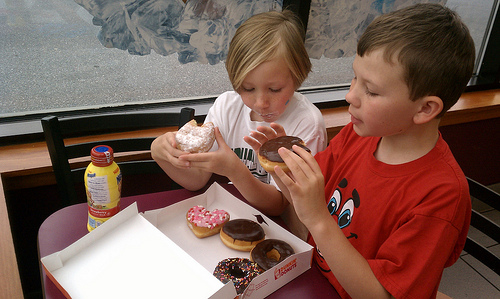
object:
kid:
[150, 10, 328, 221]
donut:
[173, 118, 216, 156]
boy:
[241, 3, 477, 298]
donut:
[255, 135, 310, 173]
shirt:
[305, 121, 472, 298]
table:
[39, 183, 342, 299]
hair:
[224, 9, 313, 94]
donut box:
[39, 181, 312, 299]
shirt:
[198, 90, 327, 193]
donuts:
[184, 204, 232, 239]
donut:
[211, 257, 265, 296]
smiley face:
[304, 178, 359, 273]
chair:
[38, 107, 195, 209]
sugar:
[255, 111, 283, 119]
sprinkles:
[224, 259, 238, 265]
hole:
[263, 249, 282, 263]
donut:
[219, 218, 265, 252]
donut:
[249, 238, 295, 272]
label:
[272, 257, 298, 280]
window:
[0, 0, 499, 123]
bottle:
[83, 145, 123, 232]